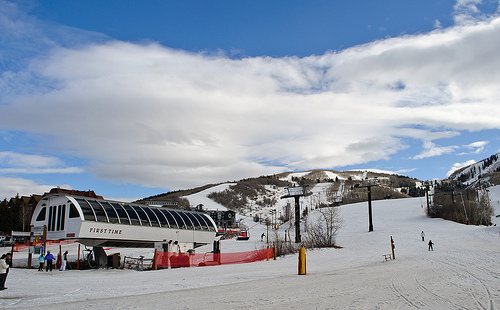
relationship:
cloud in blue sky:
[117, 65, 281, 143] [174, 8, 343, 33]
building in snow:
[30, 188, 219, 253] [173, 276, 263, 295]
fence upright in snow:
[151, 252, 289, 263] [173, 276, 263, 295]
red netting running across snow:
[151, 252, 289, 263] [173, 276, 263, 295]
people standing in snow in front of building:
[18, 244, 75, 282] [24, 238, 131, 277]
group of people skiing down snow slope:
[420, 230, 434, 251] [388, 189, 473, 299]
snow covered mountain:
[173, 276, 263, 295] [211, 169, 381, 213]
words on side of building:
[84, 223, 127, 240] [68, 194, 229, 245]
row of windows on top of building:
[83, 198, 208, 228] [68, 194, 229, 245]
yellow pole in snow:
[296, 244, 307, 275] [173, 276, 263, 295]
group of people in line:
[18, 244, 75, 282] [16, 240, 112, 266]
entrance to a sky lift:
[24, 238, 131, 277] [16, 229, 163, 266]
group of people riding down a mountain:
[420, 230, 434, 251] [211, 169, 381, 213]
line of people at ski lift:
[16, 232, 122, 299] [68, 194, 229, 245]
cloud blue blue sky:
[117, 65, 281, 143] [174, 8, 343, 33]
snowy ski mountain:
[376, 204, 424, 273] [211, 169, 381, 213]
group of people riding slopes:
[393, 192, 437, 283] [351, 187, 420, 232]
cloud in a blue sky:
[117, 65, 281, 143] [174, 8, 343, 33]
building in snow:
[27, 186, 216, 284] [173, 276, 263, 295]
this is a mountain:
[315, 185, 458, 295] [211, 169, 381, 213]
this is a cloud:
[315, 185, 458, 295] [117, 65, 281, 143]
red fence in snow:
[154, 255, 281, 266] [173, 276, 263, 295]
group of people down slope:
[420, 230, 434, 251] [388, 189, 473, 299]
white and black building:
[65, 205, 191, 238] [27, 186, 216, 284]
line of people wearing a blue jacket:
[44, 250, 56, 272] [45, 249, 52, 274]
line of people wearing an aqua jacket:
[44, 250, 56, 272] [35, 250, 46, 272]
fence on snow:
[151, 252, 289, 263] [173, 276, 263, 295]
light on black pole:
[352, 181, 378, 193] [364, 186, 373, 233]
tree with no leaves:
[450, 187, 478, 229] [423, 186, 499, 243]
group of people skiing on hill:
[420, 230, 434, 251] [393, 192, 437, 283]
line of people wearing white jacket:
[44, 250, 56, 272] [45, 249, 52, 274]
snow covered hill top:
[173, 276, 263, 295] [387, 193, 405, 227]